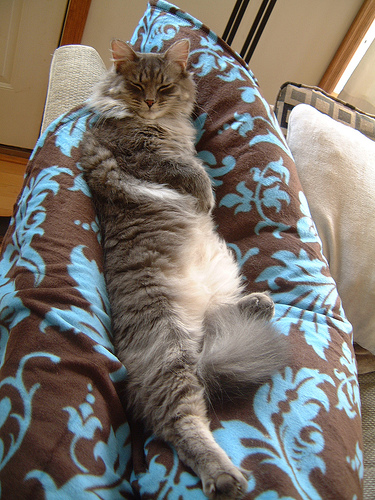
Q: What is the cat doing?
A: Lying on the couch.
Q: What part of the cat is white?
A: The stomach.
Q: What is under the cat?
A: A blanket.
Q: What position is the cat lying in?
A: On the back.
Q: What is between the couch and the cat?
A: A blanket.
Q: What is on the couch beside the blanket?
A: A beige cushion.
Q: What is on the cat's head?
A: Ears.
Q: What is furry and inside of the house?
A: A cat.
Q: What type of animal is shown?
A: Cat.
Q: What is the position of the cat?
A: Laying.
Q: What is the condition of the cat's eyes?
A: Closed.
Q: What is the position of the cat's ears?
A: Raised.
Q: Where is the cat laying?
A: On a blanket.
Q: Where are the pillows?
A: Beside the cat.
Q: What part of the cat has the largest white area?
A: Belly.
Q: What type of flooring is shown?
A: Hardwood.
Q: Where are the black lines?
A: On the wall.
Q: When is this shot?
A: Daytime.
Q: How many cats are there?
A: 1.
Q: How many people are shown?
A: 0.